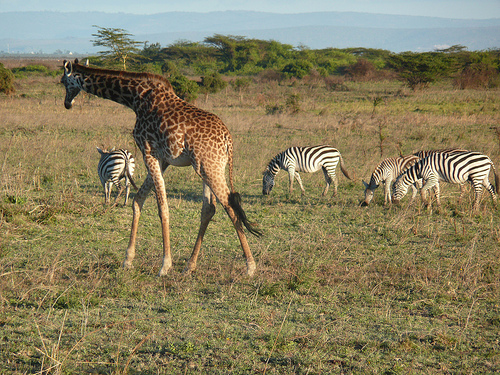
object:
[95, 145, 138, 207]
animal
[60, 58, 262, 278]
animal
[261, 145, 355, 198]
animal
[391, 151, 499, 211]
animal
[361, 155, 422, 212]
animal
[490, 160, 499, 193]
long tail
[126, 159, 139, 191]
long tail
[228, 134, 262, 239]
long tail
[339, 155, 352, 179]
long tail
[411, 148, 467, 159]
zebra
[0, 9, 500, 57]
mountains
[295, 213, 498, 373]
ground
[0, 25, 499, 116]
trees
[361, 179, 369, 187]
ear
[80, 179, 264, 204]
shadow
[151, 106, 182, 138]
spots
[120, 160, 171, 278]
legs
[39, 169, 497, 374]
grass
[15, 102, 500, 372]
land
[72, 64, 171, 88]
brown mane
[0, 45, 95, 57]
city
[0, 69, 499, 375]
fields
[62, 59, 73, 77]
ear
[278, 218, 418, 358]
ground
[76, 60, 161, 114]
neck